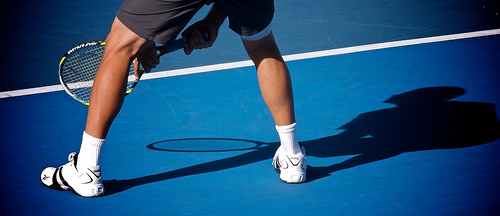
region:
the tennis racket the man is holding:
[51, 34, 194, 99]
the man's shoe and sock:
[258, 117, 308, 184]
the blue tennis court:
[4, 5, 494, 214]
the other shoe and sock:
[38, 131, 109, 202]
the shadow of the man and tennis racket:
[125, 83, 497, 183]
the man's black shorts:
[116, 2, 275, 47]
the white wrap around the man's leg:
[236, 22, 282, 41]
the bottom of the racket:
[157, 38, 207, 53]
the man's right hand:
[179, 18, 226, 58]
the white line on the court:
[3, 25, 496, 105]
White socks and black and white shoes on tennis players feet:
[30, 121, 335, 199]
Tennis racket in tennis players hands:
[45, 18, 230, 109]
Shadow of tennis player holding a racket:
[100, 75, 496, 211]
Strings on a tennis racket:
[71, 60, 96, 80]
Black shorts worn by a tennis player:
[105, 5, 291, 45]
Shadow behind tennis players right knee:
[240, 27, 302, 68]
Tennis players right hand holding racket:
[175, 12, 222, 62]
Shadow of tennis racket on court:
[140, 125, 270, 166]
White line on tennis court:
[285, 15, 496, 60]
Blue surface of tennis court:
[155, 85, 255, 126]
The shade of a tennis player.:
[97, 82, 497, 195]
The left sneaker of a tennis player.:
[39, 151, 105, 195]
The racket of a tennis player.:
[55, 36, 187, 106]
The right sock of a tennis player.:
[274, 123, 298, 152]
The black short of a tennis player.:
[115, 0, 277, 43]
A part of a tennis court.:
[0, 0, 498, 213]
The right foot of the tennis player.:
[218, 1, 308, 184]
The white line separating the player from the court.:
[0, 24, 497, 100]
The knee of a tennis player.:
[102, 30, 108, 51]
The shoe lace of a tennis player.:
[67, 151, 74, 160]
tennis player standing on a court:
[21, 0, 323, 200]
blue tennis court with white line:
[137, 56, 257, 208]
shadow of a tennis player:
[68, 75, 495, 211]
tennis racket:
[42, 22, 226, 118]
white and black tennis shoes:
[0, 115, 340, 203]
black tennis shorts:
[93, 2, 308, 49]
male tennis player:
[21, 2, 330, 199]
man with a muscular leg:
[23, 12, 154, 207]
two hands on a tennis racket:
[43, 15, 242, 116]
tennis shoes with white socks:
[33, 108, 325, 203]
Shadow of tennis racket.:
[145, 131, 266, 155]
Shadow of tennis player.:
[99, 83, 494, 199]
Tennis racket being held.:
[49, 28, 211, 108]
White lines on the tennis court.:
[2, 18, 499, 108]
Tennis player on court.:
[40, 3, 312, 197]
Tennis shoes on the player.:
[40, 153, 315, 197]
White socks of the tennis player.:
[75, 123, 305, 168]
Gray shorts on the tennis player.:
[116, 3, 276, 48]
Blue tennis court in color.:
[2, 4, 494, 212]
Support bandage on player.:
[235, 24, 279, 44]